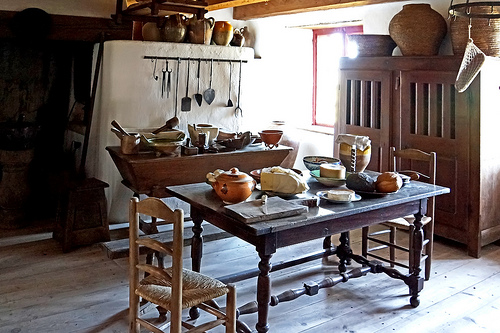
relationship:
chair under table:
[127, 185, 272, 328] [127, 104, 442, 311]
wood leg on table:
[404, 213, 425, 307] [376, 187, 432, 239]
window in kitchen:
[308, 25, 363, 130] [4, 1, 494, 328]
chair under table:
[127, 197, 237, 333] [150, 156, 445, 330]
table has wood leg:
[174, 180, 209, 202] [410, 218, 422, 305]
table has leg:
[167, 162, 429, 326] [403, 211, 425, 309]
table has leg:
[167, 162, 429, 326] [335, 230, 352, 284]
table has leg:
[167, 162, 429, 326] [251, 250, 278, 332]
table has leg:
[167, 162, 429, 326] [188, 220, 208, 272]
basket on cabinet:
[352, 28, 392, 58] [329, 55, 499, 257]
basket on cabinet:
[449, 2, 499, 57] [329, 55, 499, 257]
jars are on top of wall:
[123, 9, 249, 45] [7, 0, 199, 238]